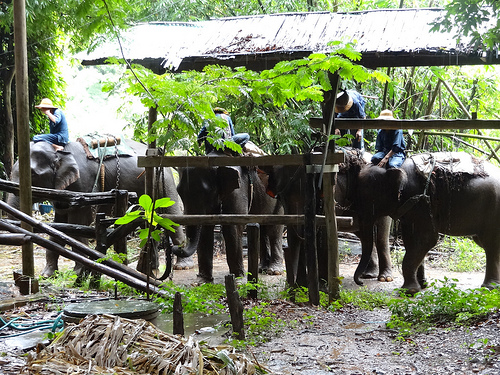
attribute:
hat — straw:
[375, 107, 395, 122]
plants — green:
[101, 44, 392, 156]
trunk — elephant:
[349, 207, 374, 287]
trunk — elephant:
[165, 193, 210, 258]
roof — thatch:
[80, 5, 499, 55]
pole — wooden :
[6, 15, 26, 259]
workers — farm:
[301, 70, 443, 203]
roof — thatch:
[81, 6, 496, 68]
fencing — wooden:
[133, 111, 497, 281]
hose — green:
[7, 301, 67, 373]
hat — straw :
[370, 107, 402, 121]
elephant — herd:
[360, 159, 497, 301]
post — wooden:
[143, 100, 160, 227]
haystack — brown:
[22, 303, 272, 374]